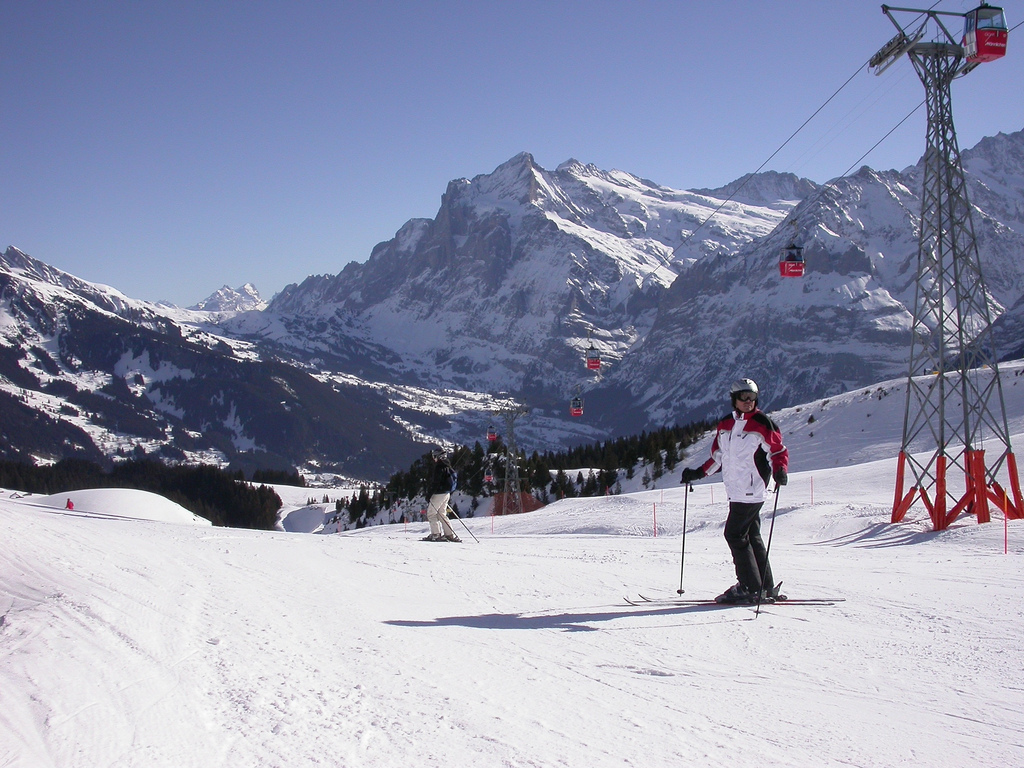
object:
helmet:
[725, 376, 760, 402]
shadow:
[374, 601, 772, 639]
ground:
[735, 690, 767, 714]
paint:
[885, 448, 1020, 533]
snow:
[788, 664, 799, 682]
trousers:
[424, 492, 452, 539]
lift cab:
[955, 4, 1013, 65]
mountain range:
[0, 132, 1022, 489]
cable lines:
[477, 7, 1023, 457]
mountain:
[9, 124, 1016, 767]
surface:
[2, 422, 1017, 761]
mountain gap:
[2, 184, 441, 322]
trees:
[351, 484, 371, 525]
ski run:
[0, 414, 1024, 718]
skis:
[604, 601, 843, 609]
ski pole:
[668, 470, 693, 600]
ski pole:
[738, 470, 789, 619]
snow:
[375, 314, 443, 360]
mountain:
[0, 102, 1019, 481]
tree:
[255, 487, 279, 528]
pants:
[422, 493, 454, 533]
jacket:
[422, 457, 456, 496]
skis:
[418, 538, 465, 544]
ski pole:
[436, 487, 483, 550]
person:
[674, 367, 802, 616]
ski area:
[0, 171, 1019, 766]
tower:
[872, 1, 1018, 529]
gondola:
[952, 5, 1009, 69]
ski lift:
[398, 1, 1021, 550]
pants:
[720, 502, 771, 597]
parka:
[692, 409, 786, 502]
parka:
[417, 460, 463, 493]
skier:
[406, 440, 461, 542]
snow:
[5, 506, 1018, 761]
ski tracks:
[6, 526, 1021, 754]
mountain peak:
[188, 280, 264, 315]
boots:
[705, 579, 771, 607]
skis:
[614, 596, 849, 605]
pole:
[746, 476, 787, 620]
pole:
[670, 461, 694, 599]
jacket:
[675, 404, 795, 508]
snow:
[194, 584, 618, 758]